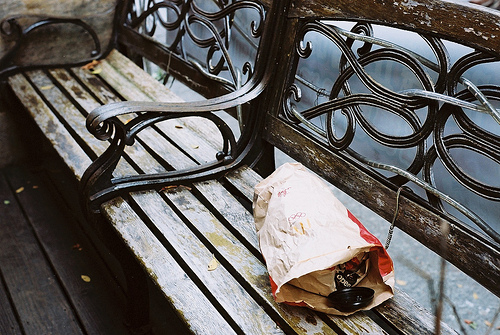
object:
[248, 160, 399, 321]
bag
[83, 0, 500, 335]
bench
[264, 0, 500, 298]
bench back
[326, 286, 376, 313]
lid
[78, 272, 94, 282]
leaf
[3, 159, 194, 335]
ground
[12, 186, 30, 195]
leaf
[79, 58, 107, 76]
leaf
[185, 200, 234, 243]
paint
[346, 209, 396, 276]
mcdonalds logo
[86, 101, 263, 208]
arm rest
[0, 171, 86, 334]
boards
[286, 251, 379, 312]
trash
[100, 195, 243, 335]
wooden slats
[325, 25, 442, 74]
ironworking cable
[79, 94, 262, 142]
bench handle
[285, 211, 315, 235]
olympics logo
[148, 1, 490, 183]
stone wall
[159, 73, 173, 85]
small lights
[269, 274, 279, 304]
trim